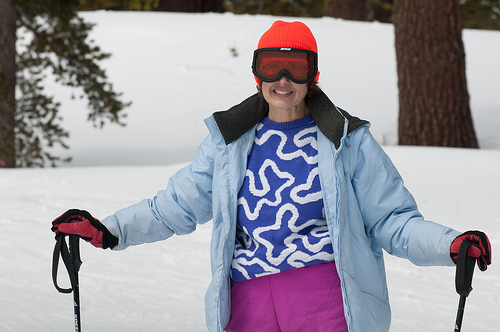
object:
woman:
[42, 11, 496, 332]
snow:
[67, 169, 139, 199]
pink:
[79, 226, 92, 234]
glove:
[47, 207, 118, 251]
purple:
[254, 146, 266, 160]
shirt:
[226, 115, 335, 281]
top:
[245, 104, 332, 138]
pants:
[209, 257, 361, 332]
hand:
[437, 227, 500, 277]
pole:
[445, 244, 481, 332]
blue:
[170, 193, 194, 208]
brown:
[409, 36, 444, 62]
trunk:
[389, 2, 485, 147]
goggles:
[248, 45, 323, 86]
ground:
[103, 16, 200, 134]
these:
[226, 281, 330, 330]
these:
[67, 36, 78, 48]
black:
[319, 111, 335, 125]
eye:
[283, 60, 306, 76]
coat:
[104, 90, 463, 332]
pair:
[220, 265, 351, 332]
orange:
[252, 18, 324, 54]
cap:
[245, 18, 323, 87]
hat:
[253, 16, 321, 52]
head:
[246, 15, 330, 125]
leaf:
[63, 27, 82, 45]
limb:
[15, 7, 72, 69]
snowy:
[138, 94, 198, 130]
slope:
[0, 7, 209, 170]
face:
[254, 42, 313, 110]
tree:
[383, 0, 485, 151]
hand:
[41, 201, 119, 255]